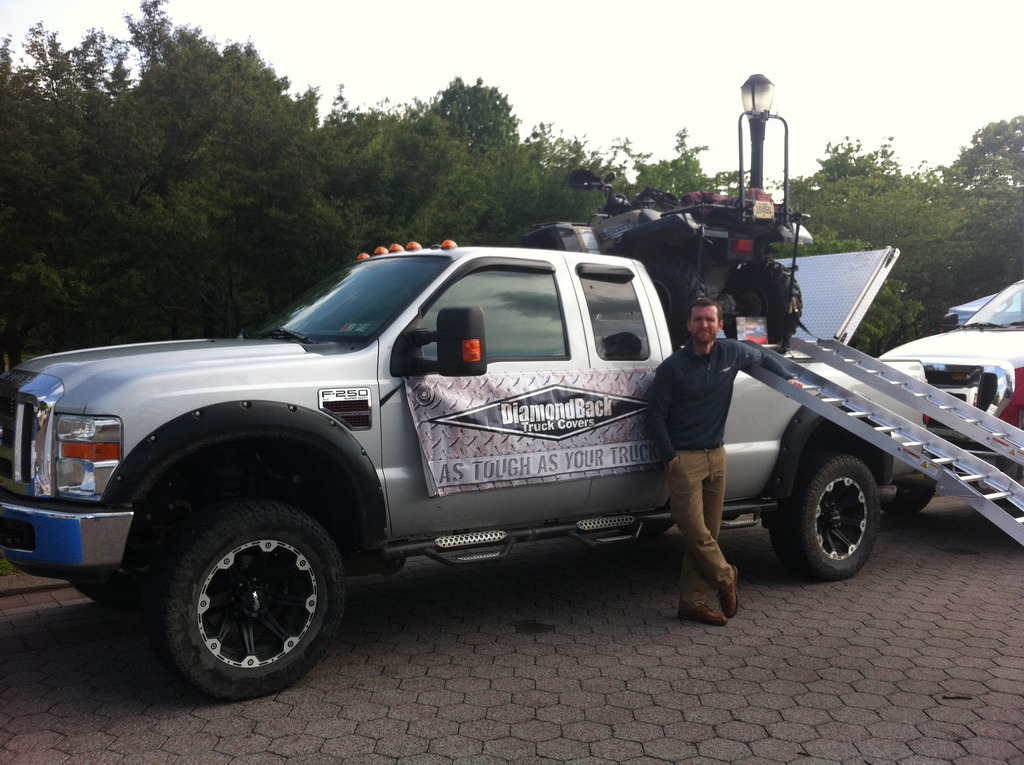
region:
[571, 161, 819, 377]
the 4 wheeler in is the truckbed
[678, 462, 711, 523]
he is wearing brown pants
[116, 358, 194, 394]
the truck is silver in color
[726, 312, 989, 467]
the ramps are leaning on the truck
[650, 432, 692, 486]
he has his hand in his pocket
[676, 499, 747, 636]
the man has his leg crossed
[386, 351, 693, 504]
the truck has a banner on it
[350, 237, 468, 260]
the light covers are orange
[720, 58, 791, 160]
the light on the pole is off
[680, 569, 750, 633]
the mans shoes are a brown color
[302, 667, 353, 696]
a tile in a floor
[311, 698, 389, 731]
a tile in a floor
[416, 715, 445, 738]
a tile in a floor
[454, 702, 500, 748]
a tile in a floor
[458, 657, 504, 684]
a tile in a floor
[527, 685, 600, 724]
a tile in a floor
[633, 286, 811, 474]
Man wearing a long sleeved blue shirt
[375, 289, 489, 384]
The back of a black side mirror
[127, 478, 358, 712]
A large round rubber tire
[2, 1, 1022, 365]
Green leaves on many trees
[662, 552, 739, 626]
A pair of brown shoes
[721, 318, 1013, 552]
Two ladders leading to a truck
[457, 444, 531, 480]
The word "TOUGH" on a sign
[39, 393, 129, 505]
A headlight on a truck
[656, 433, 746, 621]
A pair of brown pants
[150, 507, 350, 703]
Wheel of a truck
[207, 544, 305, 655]
Rim of a tire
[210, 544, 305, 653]
Silver rim of a tire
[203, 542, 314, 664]
Rim of a black tire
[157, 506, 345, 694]
Tire of a silver truck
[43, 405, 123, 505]
Headlight of a truck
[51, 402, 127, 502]
Headlight of a silver truck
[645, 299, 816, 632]
Man is facing the camera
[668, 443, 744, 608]
Pants on a man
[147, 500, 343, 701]
Tire of a truck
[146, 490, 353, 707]
Black tire of a silver truck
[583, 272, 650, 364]
Window of a truck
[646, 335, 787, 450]
A black shirt on a man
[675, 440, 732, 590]
Brown pants on a man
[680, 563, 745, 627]
Brown shoes on a man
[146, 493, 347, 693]
A front tire on a truck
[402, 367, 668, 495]
A banner on the side of a truck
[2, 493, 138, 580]
A chrome bumper on a truck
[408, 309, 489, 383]
A side mirror on a truck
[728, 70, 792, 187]
A street light behind a truck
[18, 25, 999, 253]
trees behind the truck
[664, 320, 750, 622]
a man in a black shirt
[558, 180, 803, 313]
a four wheeler in the truck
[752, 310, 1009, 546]
silver ramps on the truck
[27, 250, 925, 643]
a large silver truck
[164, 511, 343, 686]
the tire on the truck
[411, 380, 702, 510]
the sign on the truck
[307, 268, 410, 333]
the windshield on the truck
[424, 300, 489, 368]
the mirror on the truck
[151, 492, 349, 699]
A tire on a vehicle.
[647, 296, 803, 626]
A person is standing up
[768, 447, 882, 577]
A tire on a vehicle.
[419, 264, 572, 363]
A window on a vehicle.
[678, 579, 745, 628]
brown colored shoes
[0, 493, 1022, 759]
gray colored cobblestone pavement